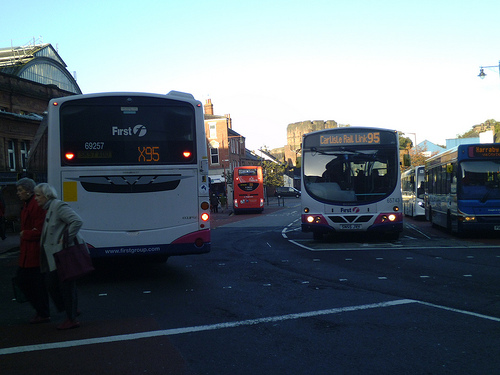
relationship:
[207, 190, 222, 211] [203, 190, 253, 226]
person on a sidewalk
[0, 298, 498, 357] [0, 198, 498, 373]
line on asphalt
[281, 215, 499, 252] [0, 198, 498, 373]
line on asphalt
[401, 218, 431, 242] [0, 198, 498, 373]
line on asphalt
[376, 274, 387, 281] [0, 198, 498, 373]
line on asphalt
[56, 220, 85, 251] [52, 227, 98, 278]
handle on bag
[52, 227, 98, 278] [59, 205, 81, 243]
bag on arm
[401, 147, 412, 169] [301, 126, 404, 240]
mirror on bus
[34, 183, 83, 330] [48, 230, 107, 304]
elderly woman holding bag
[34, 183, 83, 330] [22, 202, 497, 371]
elderly woman walking on street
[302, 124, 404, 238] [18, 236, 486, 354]
bus on road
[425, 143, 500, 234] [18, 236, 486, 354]
bus on road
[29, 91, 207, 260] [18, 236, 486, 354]
bus on road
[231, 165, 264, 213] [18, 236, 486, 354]
bus on road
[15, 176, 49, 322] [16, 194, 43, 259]
elderly woman has coat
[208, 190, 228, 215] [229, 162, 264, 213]
passengers getting on bus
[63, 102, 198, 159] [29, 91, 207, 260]
window in back of bus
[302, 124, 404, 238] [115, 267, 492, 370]
bus on road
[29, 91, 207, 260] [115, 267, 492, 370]
bus on road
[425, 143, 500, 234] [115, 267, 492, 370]
bus on road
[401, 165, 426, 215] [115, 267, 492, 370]
bus on road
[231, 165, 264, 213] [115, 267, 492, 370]
bus on road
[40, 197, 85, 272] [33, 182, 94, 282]
coat with woman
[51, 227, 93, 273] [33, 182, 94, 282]
bag with woman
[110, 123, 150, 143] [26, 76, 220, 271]
logo on bus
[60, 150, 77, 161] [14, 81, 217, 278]
light on bus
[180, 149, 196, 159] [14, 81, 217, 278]
light on bus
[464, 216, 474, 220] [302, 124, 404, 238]
headlight on bus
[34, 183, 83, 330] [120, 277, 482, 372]
elderly woman crossing road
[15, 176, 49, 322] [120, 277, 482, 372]
elderly woman crossing road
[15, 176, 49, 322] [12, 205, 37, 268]
elderly woman reading red coat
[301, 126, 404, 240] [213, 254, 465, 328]
bus stopped intersection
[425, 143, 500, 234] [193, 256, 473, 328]
bus at intersection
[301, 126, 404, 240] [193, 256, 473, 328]
bus at intersection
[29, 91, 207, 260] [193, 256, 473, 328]
bus at intersection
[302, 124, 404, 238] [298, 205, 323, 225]
bus has headlights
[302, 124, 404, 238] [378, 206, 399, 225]
bus has headlights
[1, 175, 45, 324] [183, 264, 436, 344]
elderly woman walking across road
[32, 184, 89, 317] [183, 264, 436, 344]
elderly woman walking across road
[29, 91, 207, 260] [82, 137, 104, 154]
bus has white numbers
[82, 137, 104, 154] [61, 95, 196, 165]
white numbers on window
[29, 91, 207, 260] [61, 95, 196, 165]
bus has window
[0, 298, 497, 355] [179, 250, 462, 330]
line on road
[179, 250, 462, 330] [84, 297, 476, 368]
road marking crosswalk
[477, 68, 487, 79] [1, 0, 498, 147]
lamp in sky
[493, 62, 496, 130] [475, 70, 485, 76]
pole has light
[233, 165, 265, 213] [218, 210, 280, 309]
bus on street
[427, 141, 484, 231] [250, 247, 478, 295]
bus on road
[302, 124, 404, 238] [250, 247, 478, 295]
bus on road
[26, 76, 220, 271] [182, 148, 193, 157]
bus has light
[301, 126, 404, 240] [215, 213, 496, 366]
bus driving on road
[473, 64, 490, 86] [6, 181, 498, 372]
lamp on road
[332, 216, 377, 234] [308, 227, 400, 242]
license plate on bumper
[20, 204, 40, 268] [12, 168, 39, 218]
jacket on woman